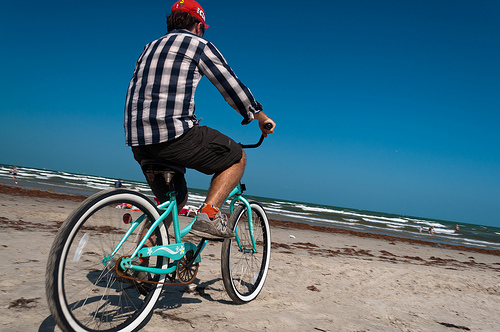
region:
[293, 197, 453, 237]
a few waves crashing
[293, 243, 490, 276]
some seawead on the beach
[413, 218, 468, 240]
a few people in the water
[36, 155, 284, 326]
a bright blue bike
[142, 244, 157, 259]
a painted white flower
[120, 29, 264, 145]
a long sleeved checkered shirt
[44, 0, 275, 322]
a man riding a bike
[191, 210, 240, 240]
a dark grey sneaker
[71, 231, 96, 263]
a white reflector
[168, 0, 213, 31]
a bright red baseball cap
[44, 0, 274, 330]
man riding on a light blue bicycle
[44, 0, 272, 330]
man riding a bicycle on the beach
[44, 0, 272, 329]
man riding a bike in the sand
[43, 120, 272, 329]
light blue bicycle with designs on it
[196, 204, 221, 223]
orange sock on the man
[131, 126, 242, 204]
black shorts on the man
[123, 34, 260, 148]
black and white flannel shirt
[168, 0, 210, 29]
red hat on the man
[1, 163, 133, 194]
people walking on the beach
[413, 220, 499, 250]
people swimming in the ocean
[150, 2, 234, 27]
man has red hat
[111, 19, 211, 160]
man has checked shirt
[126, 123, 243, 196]
man has black shorts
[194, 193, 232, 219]
man has orange socks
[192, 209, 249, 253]
man has grey shoes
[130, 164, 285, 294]
bike has blue frame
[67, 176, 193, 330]
white rims on tires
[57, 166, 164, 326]
bike has black tires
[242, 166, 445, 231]
white waves on water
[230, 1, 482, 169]
sky is blue and cloudless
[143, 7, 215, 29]
man has brown hair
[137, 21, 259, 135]
black and white shirt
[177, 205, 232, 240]
man has orange socks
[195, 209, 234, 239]
man has grey shoes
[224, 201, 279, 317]
black tires on bike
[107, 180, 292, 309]
blue frame on bike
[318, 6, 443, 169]
sky is blue and clear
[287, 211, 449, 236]
white waves on water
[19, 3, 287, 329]
person riding a bike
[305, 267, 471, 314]
sand area of beach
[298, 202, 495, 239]
water area of beach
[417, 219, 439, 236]
people in water area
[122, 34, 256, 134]
plaid shirt on person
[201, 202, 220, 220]
sock on person's foot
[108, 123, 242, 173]
shorts on person on bike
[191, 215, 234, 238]
athletic shoe on person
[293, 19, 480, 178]
clear sky with no clouds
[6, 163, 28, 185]
other people playing on beach